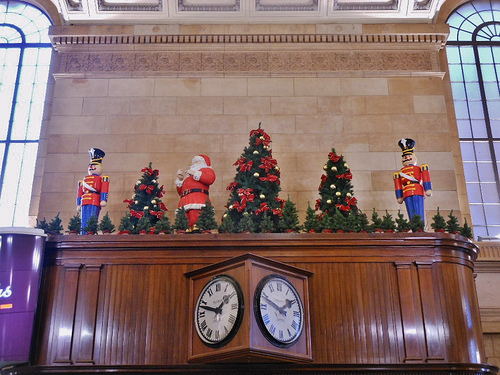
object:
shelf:
[54, 220, 451, 372]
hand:
[191, 303, 217, 316]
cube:
[144, 234, 322, 370]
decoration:
[394, 132, 442, 222]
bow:
[225, 180, 242, 191]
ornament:
[314, 161, 361, 207]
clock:
[250, 251, 318, 359]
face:
[190, 272, 244, 346]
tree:
[217, 122, 286, 231]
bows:
[252, 203, 270, 216]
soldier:
[386, 127, 432, 229]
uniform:
[387, 165, 436, 224]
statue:
[163, 148, 219, 228]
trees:
[460, 201, 474, 238]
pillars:
[46, 259, 79, 363]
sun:
[3, 49, 33, 139]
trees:
[256, 213, 274, 235]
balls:
[248, 147, 265, 155]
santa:
[164, 146, 214, 228]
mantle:
[41, 234, 481, 373]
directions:
[186, 256, 314, 362]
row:
[37, 203, 481, 244]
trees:
[371, 211, 383, 230]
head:
[188, 148, 218, 178]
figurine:
[172, 146, 230, 235]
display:
[44, 130, 480, 242]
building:
[5, 5, 498, 372]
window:
[443, 0, 499, 243]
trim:
[443, 37, 496, 51]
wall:
[27, 24, 469, 239]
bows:
[234, 158, 249, 165]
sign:
[3, 231, 46, 365]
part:
[8, 242, 28, 273]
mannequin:
[70, 139, 116, 233]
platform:
[40, 226, 491, 370]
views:
[173, 258, 250, 355]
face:
[263, 286, 307, 337]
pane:
[8, 46, 21, 138]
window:
[0, 2, 56, 227]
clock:
[190, 273, 244, 347]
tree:
[113, 159, 173, 235]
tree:
[287, 145, 377, 236]